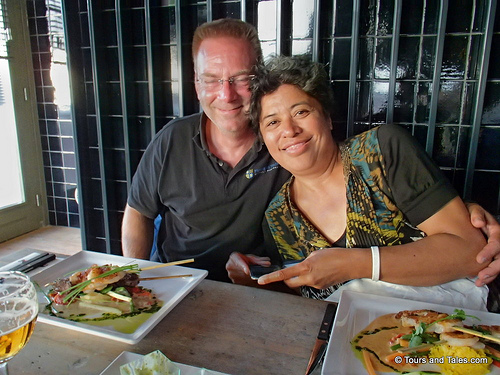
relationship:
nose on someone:
[282, 118, 298, 138] [222, 58, 490, 305]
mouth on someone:
[275, 136, 315, 159] [222, 58, 490, 305]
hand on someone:
[256, 246, 372, 292] [222, 58, 490, 305]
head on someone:
[239, 59, 340, 179] [222, 58, 490, 305]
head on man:
[182, 14, 259, 140] [113, 17, 259, 277]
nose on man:
[218, 78, 232, 108] [113, 17, 259, 277]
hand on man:
[465, 201, 498, 289] [115, 16, 498, 289]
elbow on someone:
[456, 225, 496, 283] [222, 58, 490, 305]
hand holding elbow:
[465, 201, 498, 289] [456, 225, 496, 283]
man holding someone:
[115, 16, 498, 289] [222, 58, 490, 305]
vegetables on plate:
[52, 257, 156, 322] [27, 245, 212, 345]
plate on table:
[27, 245, 212, 345] [226, 294, 316, 373]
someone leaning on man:
[222, 58, 490, 305] [115, 16, 498, 289]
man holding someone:
[115, 16, 498, 289] [249, 58, 482, 305]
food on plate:
[351, 303, 494, 370] [310, 286, 497, 372]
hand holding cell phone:
[221, 250, 273, 290] [242, 253, 282, 282]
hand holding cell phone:
[252, 241, 373, 288] [242, 253, 282, 282]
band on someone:
[368, 243, 382, 282] [222, 58, 490, 305]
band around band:
[368, 243, 382, 282] [368, 243, 382, 282]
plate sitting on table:
[27, 245, 212, 345] [12, 250, 499, 373]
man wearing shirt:
[115, 16, 498, 305] [122, 110, 291, 275]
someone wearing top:
[222, 58, 490, 305] [252, 120, 462, 294]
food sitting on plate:
[47, 255, 163, 325] [27, 245, 212, 345]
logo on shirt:
[244, 166, 254, 178] [125, 114, 301, 294]